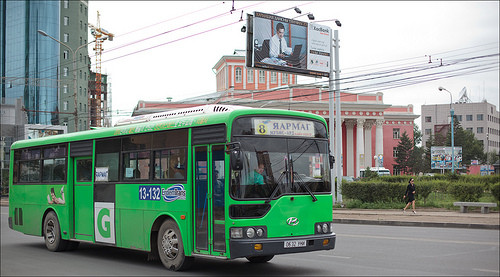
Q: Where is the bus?
A: On the road.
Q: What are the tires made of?
A: Rubber.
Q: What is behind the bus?
A: A red building.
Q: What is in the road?
A: A bus.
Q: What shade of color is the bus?
A: Green.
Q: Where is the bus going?
A: Down the road.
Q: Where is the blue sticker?
A: On the bus.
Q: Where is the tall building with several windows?
A: Behind the bus.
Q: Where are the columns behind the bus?
A: By the pink building.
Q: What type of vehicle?
A: A bus.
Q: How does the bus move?
A: Wheels.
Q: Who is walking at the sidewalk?
A: A woman.